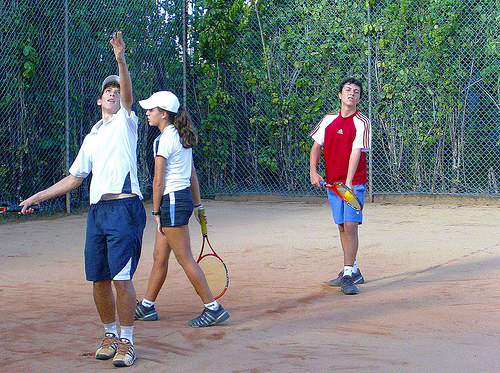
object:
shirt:
[307, 111, 371, 186]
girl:
[133, 90, 229, 327]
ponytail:
[173, 107, 196, 148]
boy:
[19, 29, 145, 368]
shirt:
[68, 99, 143, 201]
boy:
[306, 78, 370, 297]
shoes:
[340, 275, 360, 295]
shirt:
[153, 122, 191, 197]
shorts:
[329, 183, 368, 226]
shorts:
[84, 195, 147, 282]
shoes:
[111, 338, 135, 367]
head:
[338, 76, 363, 107]